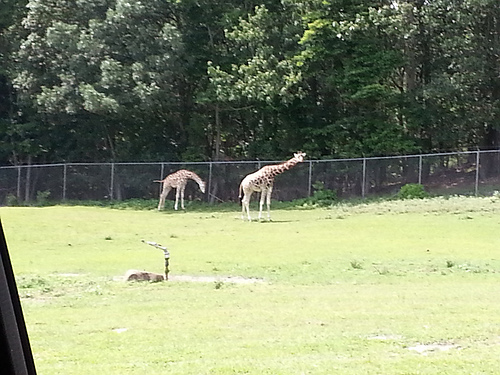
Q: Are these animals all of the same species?
A: Yes, all the animals are giraffes.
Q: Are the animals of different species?
A: No, all the animals are giraffes.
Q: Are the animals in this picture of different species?
A: No, all the animals are giraffes.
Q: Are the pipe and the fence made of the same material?
A: Yes, both the pipe and the fence are made of metal.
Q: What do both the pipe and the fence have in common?
A: The material, both the pipe and the fence are metallic.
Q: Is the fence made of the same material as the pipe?
A: Yes, both the fence and the pipe are made of metal.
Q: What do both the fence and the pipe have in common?
A: The material, both the fence and the pipe are metallic.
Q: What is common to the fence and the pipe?
A: The material, both the fence and the pipe are metallic.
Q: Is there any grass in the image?
A: Yes, there is grass.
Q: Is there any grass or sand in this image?
A: Yes, there is grass.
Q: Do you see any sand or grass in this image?
A: Yes, there is grass.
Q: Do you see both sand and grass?
A: No, there is grass but no sand.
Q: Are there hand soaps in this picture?
A: No, there are no hand soaps.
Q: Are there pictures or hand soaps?
A: No, there are no hand soaps or pictures.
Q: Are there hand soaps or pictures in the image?
A: No, there are no hand soaps or pictures.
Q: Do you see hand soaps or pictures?
A: No, there are no hand soaps or pictures.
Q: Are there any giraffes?
A: Yes, there is a giraffe.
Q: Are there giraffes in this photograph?
A: Yes, there is a giraffe.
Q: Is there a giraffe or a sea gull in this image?
A: Yes, there is a giraffe.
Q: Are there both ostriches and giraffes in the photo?
A: No, there is a giraffe but no ostriches.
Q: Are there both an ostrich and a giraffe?
A: No, there is a giraffe but no ostriches.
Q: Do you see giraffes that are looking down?
A: Yes, there is a giraffe that is looking down.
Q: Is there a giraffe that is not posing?
A: Yes, there is a giraffe that is looking down.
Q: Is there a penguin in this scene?
A: No, there are no penguins.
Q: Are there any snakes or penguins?
A: No, there are no penguins or snakes.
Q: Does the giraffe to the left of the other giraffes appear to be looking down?
A: Yes, the giraffe is looking down.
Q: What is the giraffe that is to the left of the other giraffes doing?
A: The giraffe is looking down.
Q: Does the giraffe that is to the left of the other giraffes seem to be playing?
A: No, the giraffe is looking down.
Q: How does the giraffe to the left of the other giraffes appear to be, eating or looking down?
A: The giraffe is looking down.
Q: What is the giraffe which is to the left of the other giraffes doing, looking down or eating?
A: The giraffe is looking down.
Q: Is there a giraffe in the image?
A: Yes, there are giraffes.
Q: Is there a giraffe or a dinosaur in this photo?
A: Yes, there are giraffes.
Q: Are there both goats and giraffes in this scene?
A: No, there are giraffes but no goats.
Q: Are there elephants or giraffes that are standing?
A: Yes, the giraffes are standing.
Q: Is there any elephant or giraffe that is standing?
A: Yes, the giraffes are standing.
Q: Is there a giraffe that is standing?
A: Yes, there are giraffes that are standing.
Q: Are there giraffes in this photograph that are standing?
A: Yes, there are giraffes that are standing.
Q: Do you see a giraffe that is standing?
A: Yes, there are giraffes that are standing.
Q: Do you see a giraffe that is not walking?
A: Yes, there are giraffes that are standing .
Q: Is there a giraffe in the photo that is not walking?
A: Yes, there are giraffes that are standing.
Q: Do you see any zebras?
A: No, there are no zebras.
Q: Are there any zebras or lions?
A: No, there are no zebras or lions.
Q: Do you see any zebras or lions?
A: No, there are no zebras or lions.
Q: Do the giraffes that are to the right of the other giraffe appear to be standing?
A: Yes, the giraffes are standing.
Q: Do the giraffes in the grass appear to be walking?
A: No, the giraffes are standing.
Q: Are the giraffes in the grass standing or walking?
A: The giraffes are standing.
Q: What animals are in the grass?
A: The animals are giraffes.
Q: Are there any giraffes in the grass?
A: Yes, there are giraffes in the grass.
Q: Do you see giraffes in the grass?
A: Yes, there are giraffes in the grass.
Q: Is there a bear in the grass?
A: No, there are giraffes in the grass.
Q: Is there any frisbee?
A: No, there are no frisbees.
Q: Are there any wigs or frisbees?
A: No, there are no frisbees or wigs.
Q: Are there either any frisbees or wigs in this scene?
A: No, there are no frisbees or wigs.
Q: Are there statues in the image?
A: No, there are no statues.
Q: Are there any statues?
A: No, there are no statues.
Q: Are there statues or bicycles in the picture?
A: No, there are no statues or bicycles.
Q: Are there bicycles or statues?
A: No, there are no statues or bicycles.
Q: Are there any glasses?
A: No, there are no glasses.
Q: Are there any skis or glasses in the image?
A: No, there are no glasses or skis.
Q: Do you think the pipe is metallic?
A: Yes, the pipe is metallic.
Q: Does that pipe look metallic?
A: Yes, the pipe is metallic.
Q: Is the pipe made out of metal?
A: Yes, the pipe is made of metal.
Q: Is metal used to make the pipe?
A: Yes, the pipe is made of metal.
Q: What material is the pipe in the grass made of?
A: The pipe is made of metal.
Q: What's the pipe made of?
A: The pipe is made of metal.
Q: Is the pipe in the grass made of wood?
A: No, the pipe is made of metal.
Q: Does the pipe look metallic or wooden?
A: The pipe is metallic.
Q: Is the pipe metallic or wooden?
A: The pipe is metallic.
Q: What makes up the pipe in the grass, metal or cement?
A: The pipe is made of metal.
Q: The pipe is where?
A: The pipe is in the grass.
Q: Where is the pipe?
A: The pipe is in the grass.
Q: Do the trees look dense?
A: Yes, the trees are dense.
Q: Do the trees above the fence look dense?
A: Yes, the trees are dense.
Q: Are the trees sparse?
A: No, the trees are dense.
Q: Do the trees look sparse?
A: No, the trees are dense.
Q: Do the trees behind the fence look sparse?
A: No, the trees are dense.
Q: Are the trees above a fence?
A: Yes, the trees are above a fence.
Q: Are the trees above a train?
A: No, the trees are above a fence.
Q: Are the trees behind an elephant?
A: No, the trees are behind a fence.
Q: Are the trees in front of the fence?
A: No, the trees are behind the fence.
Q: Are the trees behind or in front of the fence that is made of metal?
A: The trees are behind the fence.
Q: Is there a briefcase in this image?
A: No, there are no briefcases.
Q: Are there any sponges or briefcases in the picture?
A: No, there are no briefcases or sponges.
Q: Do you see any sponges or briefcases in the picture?
A: No, there are no briefcases or sponges.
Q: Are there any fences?
A: Yes, there is a fence.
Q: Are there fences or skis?
A: Yes, there is a fence.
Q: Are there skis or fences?
A: Yes, there is a fence.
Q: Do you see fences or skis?
A: Yes, there is a fence.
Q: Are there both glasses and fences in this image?
A: No, there is a fence but no glasses.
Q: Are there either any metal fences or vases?
A: Yes, there is a metal fence.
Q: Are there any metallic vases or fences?
A: Yes, there is a metal fence.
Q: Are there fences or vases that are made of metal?
A: Yes, the fence is made of metal.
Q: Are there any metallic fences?
A: Yes, there is a metal fence.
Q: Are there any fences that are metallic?
A: Yes, there is a fence that is metallic.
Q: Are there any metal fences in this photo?
A: Yes, there is a fence that is made of metal.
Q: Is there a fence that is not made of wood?
A: Yes, there is a fence that is made of metal.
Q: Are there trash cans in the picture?
A: No, there are no trash cans.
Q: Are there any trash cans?
A: No, there are no trash cans.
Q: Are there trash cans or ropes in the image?
A: No, there are no trash cans or ropes.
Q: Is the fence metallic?
A: Yes, the fence is metallic.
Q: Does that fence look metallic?
A: Yes, the fence is metallic.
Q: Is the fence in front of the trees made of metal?
A: Yes, the fence is made of metal.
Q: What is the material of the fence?
A: The fence is made of metal.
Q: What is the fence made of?
A: The fence is made of metal.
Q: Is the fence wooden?
A: No, the fence is metallic.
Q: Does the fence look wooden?
A: No, the fence is metallic.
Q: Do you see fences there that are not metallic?
A: No, there is a fence but it is metallic.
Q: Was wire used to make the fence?
A: No, the fence is made of metal.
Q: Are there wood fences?
A: No, there is a fence but it is made of metal.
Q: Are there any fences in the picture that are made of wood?
A: No, there is a fence but it is made of metal.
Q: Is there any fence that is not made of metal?
A: No, there is a fence but it is made of metal.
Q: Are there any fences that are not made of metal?
A: No, there is a fence but it is made of metal.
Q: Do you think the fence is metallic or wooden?
A: The fence is metallic.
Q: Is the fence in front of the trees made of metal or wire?
A: The fence is made of metal.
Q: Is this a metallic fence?
A: Yes, this is a metallic fence.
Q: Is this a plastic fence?
A: No, this is a metallic fence.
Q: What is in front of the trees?
A: The fence is in front of the trees.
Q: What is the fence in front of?
A: The fence is in front of the trees.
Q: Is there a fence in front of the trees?
A: Yes, there is a fence in front of the trees.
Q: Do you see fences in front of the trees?
A: Yes, there is a fence in front of the trees.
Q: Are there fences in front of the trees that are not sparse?
A: Yes, there is a fence in front of the trees.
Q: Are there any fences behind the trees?
A: No, the fence is in front of the trees.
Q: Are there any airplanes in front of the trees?
A: No, there is a fence in front of the trees.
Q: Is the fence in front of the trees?
A: Yes, the fence is in front of the trees.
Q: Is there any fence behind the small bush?
A: Yes, there is a fence behind the bush.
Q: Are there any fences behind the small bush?
A: Yes, there is a fence behind the bush.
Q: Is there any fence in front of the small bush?
A: No, the fence is behind the shrub.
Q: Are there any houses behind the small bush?
A: No, there is a fence behind the shrub.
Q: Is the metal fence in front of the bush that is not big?
A: No, the fence is behind the bush.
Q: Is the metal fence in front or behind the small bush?
A: The fence is behind the shrub.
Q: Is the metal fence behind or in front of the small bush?
A: The fence is behind the shrub.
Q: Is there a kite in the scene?
A: No, there are no kites.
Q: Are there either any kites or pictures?
A: No, there are no kites or pictures.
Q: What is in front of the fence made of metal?
A: The bush is in front of the fence.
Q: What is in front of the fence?
A: The bush is in front of the fence.